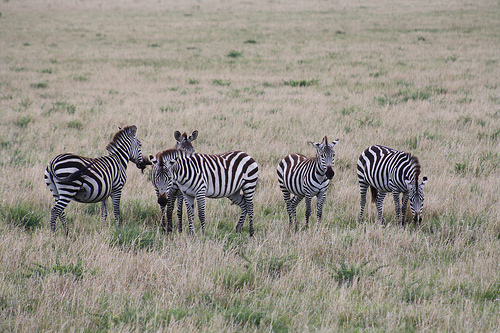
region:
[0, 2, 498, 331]
Five zebras standing in an open field.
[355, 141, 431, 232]
A zebra to the right of four other zebras.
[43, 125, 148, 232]
A zebra to the left of four other zebras.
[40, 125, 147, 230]
A zebra facing right.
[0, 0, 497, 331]
Tan and green grass.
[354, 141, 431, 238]
A zebra grazing in a field.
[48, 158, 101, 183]
A zebra's tail swishing to the right.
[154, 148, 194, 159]
Hair on the back of a zebra's neck.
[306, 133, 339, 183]
A zebra's head.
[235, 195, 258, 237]
A zebra's legs touching one another.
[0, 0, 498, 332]
a large grassy field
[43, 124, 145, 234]
a zebra on the far left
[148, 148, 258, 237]
a zebra in the center left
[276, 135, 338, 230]
a zebra in the center right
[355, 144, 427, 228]
a zebra on the far right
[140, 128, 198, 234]
a zebra behind the others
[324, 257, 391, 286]
a green bush in the grass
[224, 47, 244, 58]
a green bush in the background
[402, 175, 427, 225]
the right zebra's head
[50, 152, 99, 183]
the left zebra's tail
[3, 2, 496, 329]
brown and green grass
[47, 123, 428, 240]
group of standing zebra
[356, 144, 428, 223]
bent neck of grazing zebra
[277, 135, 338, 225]
zebra looking at camera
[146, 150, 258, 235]
zebra with head down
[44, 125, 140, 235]
zebra with wagging tail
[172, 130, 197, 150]
rounded ears on head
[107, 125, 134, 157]
mane on zebra neck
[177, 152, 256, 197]
stripes on zebra body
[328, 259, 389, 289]
patch of green weeds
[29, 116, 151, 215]
A zebra standing with it's back to the camera.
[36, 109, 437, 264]
A group of zebras just standing there.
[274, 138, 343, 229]
A cute little zebra looking confused.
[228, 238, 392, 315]
A patch of almost dead grass.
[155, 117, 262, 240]
Two zebras just standing around.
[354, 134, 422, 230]
A zebra eating the almost dead grass.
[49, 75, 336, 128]
The background of the zebras.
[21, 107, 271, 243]
Three zebras just chilling out.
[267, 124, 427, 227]
Two nervous looking zebras.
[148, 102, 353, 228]
Three zebras hanging out in the grass.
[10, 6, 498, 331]
five zebras on the savannah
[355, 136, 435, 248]
the zebra is grazing on the field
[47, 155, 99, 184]
the zebra's black tail is swaying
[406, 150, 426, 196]
the mane of the zebra is black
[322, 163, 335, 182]
the snout of the animal is black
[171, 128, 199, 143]
the ears of the zebra are black fur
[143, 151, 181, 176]
black and white stripes are on the ears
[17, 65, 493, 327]
patches of green are on the plane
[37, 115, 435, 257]
a herd of zebra are resting in the field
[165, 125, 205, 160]
a zebra is a lookout in the rear